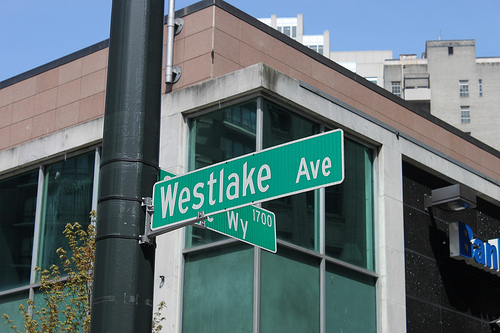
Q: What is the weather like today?
A: It is cloudless.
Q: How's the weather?
A: It is cloudless.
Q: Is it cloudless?
A: Yes, it is cloudless.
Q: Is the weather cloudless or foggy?
A: It is cloudless.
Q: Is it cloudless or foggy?
A: It is cloudless.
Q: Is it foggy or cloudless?
A: It is cloudless.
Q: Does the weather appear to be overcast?
A: No, it is cloudless.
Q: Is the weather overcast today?
A: No, it is cloudless.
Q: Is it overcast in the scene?
A: No, it is cloudless.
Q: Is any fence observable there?
A: No, there are no fences.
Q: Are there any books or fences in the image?
A: No, there are no fences or books.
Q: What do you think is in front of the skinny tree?
A: The pole is in front of the tree.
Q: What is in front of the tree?
A: The pole is in front of the tree.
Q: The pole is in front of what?
A: The pole is in front of the tree.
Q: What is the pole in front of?
A: The pole is in front of the tree.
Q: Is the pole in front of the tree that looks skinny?
A: Yes, the pole is in front of the tree.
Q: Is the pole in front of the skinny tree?
A: Yes, the pole is in front of the tree.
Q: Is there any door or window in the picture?
A: Yes, there is a window.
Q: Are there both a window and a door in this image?
A: No, there is a window but no doors.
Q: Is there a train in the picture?
A: No, there are no trains.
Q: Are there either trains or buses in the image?
A: No, there are no trains or buses.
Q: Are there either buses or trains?
A: No, there are no trains or buses.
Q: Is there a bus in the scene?
A: No, there are no buses.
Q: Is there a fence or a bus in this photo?
A: No, there are no buses or fences.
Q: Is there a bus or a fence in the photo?
A: No, there are no buses or fences.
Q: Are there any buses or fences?
A: No, there are no buses or fences.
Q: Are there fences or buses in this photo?
A: No, there are no buses or fences.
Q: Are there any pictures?
A: No, there are no pictures.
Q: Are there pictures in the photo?
A: No, there are no pictures.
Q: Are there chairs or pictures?
A: No, there are no pictures or chairs.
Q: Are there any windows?
A: Yes, there is a window.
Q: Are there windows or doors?
A: Yes, there is a window.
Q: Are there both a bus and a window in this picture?
A: No, there is a window but no buses.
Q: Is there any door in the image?
A: No, there are no doors.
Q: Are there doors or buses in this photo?
A: No, there are no doors or buses.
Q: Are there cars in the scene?
A: No, there are no cars.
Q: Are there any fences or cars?
A: No, there are no cars or fences.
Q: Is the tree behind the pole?
A: Yes, the tree is behind the pole.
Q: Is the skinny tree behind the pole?
A: Yes, the tree is behind the pole.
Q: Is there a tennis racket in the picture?
A: No, there are no rackets.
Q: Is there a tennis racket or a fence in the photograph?
A: No, there are no rackets or fences.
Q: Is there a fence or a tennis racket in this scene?
A: No, there are no rackets or fences.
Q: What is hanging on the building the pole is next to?
A: The logo is hanging on the building.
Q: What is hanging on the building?
A: The logo is hanging on the building.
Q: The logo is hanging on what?
A: The logo is hanging on the building.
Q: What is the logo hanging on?
A: The logo is hanging on the building.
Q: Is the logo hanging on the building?
A: Yes, the logo is hanging on the building.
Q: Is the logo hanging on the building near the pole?
A: Yes, the logo is hanging on the building.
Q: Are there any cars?
A: No, there are no cars.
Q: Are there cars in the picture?
A: No, there are no cars.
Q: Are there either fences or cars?
A: No, there are no cars or fences.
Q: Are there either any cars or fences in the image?
A: No, there are no cars or fences.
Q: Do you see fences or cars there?
A: No, there are no cars or fences.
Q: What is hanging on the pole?
A: The sign is hanging on the pole.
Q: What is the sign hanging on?
A: The sign is hanging on the pole.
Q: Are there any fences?
A: No, there are no fences.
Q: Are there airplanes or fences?
A: No, there are no fences or airplanes.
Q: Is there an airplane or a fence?
A: No, there are no fences or airplanes.